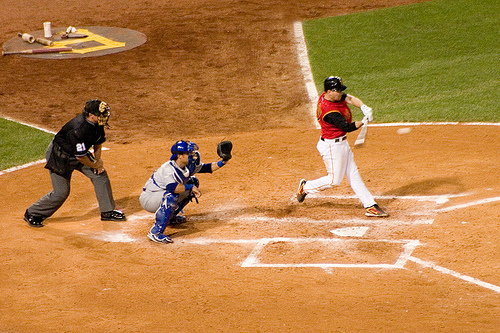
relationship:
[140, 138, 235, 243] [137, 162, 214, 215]
catcher in uniform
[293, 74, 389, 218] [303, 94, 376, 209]
player in uniform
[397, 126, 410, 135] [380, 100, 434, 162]
baseball in air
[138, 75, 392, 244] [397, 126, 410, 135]
players playing baseball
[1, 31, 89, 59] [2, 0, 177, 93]
bats in ground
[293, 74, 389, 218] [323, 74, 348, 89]
player wearing headgear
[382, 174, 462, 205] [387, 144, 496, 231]
shadow on ground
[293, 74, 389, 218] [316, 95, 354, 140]
player in red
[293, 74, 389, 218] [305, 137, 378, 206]
player in pants